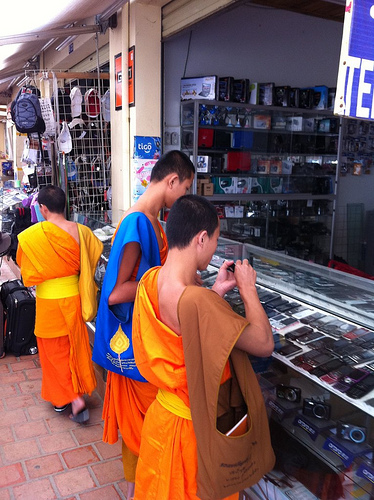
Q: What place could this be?
A: It is a shop.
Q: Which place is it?
A: It is a shop.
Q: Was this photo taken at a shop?
A: Yes, it was taken in a shop.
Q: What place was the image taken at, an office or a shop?
A: It was taken at a shop.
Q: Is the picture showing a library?
A: No, the picture is showing a shop.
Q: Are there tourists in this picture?
A: No, there are no tourists.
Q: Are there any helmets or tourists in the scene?
A: No, there are no tourists or helmets.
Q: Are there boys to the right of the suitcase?
A: No, there is a man to the right of the suitcase.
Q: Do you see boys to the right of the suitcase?
A: No, there is a man to the right of the suitcase.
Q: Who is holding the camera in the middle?
A: The man is holding the camera.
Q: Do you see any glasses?
A: No, there are no glasses.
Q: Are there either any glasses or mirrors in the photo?
A: No, there are no glasses or mirrors.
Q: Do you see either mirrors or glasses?
A: No, there are no glasses or mirrors.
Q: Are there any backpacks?
A: Yes, there is a backpack.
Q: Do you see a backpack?
A: Yes, there is a backpack.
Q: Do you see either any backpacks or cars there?
A: Yes, there is a backpack.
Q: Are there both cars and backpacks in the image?
A: No, there is a backpack but no cars.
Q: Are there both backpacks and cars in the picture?
A: No, there is a backpack but no cars.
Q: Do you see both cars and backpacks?
A: No, there is a backpack but no cars.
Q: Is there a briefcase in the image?
A: No, there are no briefcases.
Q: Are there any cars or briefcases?
A: No, there are no briefcases or cars.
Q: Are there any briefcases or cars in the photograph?
A: No, there are no briefcases or cars.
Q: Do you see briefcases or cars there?
A: No, there are no briefcases or cars.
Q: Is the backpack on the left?
A: Yes, the backpack is on the left of the image.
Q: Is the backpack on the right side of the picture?
A: No, the backpack is on the left of the image.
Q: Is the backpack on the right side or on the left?
A: The backpack is on the left of the image.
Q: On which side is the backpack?
A: The backpack is on the left of the image.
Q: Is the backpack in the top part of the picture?
A: Yes, the backpack is in the top of the image.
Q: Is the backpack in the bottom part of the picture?
A: No, the backpack is in the top of the image.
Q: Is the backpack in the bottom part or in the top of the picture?
A: The backpack is in the top of the image.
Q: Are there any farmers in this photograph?
A: No, there are no farmers.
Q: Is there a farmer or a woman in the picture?
A: No, there are no farmers or women.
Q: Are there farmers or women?
A: No, there are no farmers or women.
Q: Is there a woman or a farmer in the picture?
A: No, there are no farmers or women.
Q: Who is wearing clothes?
A: The man is wearing clothes.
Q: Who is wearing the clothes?
A: The man is wearing clothes.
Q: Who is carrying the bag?
A: The man is carrying the bag.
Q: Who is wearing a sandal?
A: The man is wearing a sandal.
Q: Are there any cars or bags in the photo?
A: Yes, there is a bag.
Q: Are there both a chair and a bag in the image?
A: No, there is a bag but no chairs.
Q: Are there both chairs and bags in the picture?
A: No, there is a bag but no chairs.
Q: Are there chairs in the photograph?
A: No, there are no chairs.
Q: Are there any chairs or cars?
A: No, there are no chairs or cars.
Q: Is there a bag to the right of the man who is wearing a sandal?
A: Yes, there is a bag to the right of the man.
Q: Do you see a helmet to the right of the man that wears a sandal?
A: No, there is a bag to the right of the man.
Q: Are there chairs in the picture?
A: No, there are no chairs.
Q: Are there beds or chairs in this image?
A: No, there are no chairs or beds.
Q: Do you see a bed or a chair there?
A: No, there are no chairs or beds.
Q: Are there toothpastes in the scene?
A: No, there are no toothpastes.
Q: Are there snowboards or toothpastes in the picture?
A: No, there are no toothpastes or snowboards.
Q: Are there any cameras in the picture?
A: Yes, there is a camera.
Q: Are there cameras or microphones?
A: Yes, there is a camera.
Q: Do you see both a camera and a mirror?
A: No, there is a camera but no mirrors.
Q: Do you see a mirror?
A: No, there are no mirrors.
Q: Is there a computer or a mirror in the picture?
A: No, there are no mirrors or computers.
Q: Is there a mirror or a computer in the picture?
A: No, there are no mirrors or computers.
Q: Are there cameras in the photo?
A: Yes, there is a camera.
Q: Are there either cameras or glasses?
A: Yes, there is a camera.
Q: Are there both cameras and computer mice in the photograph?
A: No, there is a camera but no computer mice.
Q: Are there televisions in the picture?
A: No, there are no televisions.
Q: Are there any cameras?
A: Yes, there is a camera.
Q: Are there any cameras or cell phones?
A: Yes, there is a camera.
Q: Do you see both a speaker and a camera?
A: No, there is a camera but no speakers.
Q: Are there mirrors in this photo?
A: No, there are no mirrors.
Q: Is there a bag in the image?
A: Yes, there is a bag.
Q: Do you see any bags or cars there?
A: Yes, there is a bag.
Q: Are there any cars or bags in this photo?
A: Yes, there is a bag.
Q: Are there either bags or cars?
A: Yes, there is a bag.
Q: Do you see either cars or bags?
A: Yes, there is a bag.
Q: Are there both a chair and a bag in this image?
A: No, there is a bag but no chairs.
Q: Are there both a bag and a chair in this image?
A: No, there is a bag but no chairs.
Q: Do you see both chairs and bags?
A: No, there is a bag but no chairs.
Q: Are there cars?
A: No, there are no cars.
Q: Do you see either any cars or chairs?
A: No, there are no cars or chairs.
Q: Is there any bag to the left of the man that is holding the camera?
A: Yes, there is a bag to the left of the man.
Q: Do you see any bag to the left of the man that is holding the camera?
A: Yes, there is a bag to the left of the man.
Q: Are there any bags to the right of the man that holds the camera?
A: No, the bag is to the left of the man.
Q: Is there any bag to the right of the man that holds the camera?
A: No, the bag is to the left of the man.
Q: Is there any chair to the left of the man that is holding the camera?
A: No, there is a bag to the left of the man.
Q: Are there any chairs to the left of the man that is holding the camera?
A: No, there is a bag to the left of the man.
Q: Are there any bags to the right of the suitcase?
A: Yes, there is a bag to the right of the suitcase.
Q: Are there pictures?
A: No, there are no pictures.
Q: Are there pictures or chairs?
A: No, there are no pictures or chairs.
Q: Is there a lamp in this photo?
A: No, there are no lamps.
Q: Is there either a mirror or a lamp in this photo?
A: No, there are no lamps or mirrors.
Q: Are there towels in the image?
A: No, there are no towels.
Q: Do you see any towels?
A: No, there are no towels.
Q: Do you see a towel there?
A: No, there are no towels.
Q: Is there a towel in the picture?
A: No, there are no towels.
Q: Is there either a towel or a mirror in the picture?
A: No, there are no towels or mirrors.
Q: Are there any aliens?
A: No, there are no aliens.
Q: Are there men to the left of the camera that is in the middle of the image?
A: Yes, there is a man to the left of the camera.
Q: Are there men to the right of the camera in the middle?
A: No, the man is to the left of the camera.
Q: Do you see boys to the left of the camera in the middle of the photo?
A: No, there is a man to the left of the camera.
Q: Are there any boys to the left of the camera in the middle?
A: No, there is a man to the left of the camera.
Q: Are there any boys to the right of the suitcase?
A: No, there is a man to the right of the suitcase.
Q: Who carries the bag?
A: The man carries the bag.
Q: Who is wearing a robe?
A: The man is wearing a robe.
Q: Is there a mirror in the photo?
A: No, there are no mirrors.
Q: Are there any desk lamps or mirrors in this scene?
A: No, there are no mirrors or desk lamps.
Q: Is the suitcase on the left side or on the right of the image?
A: The suitcase is on the left of the image.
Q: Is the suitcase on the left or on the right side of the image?
A: The suitcase is on the left of the image.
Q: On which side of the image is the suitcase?
A: The suitcase is on the left of the image.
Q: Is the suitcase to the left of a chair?
A: No, the suitcase is to the left of the bag.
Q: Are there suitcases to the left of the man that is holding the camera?
A: Yes, there is a suitcase to the left of the man.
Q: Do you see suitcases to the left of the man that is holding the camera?
A: Yes, there is a suitcase to the left of the man.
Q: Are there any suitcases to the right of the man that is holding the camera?
A: No, the suitcase is to the left of the man.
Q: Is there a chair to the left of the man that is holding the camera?
A: No, there is a suitcase to the left of the man.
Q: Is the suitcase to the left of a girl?
A: No, the suitcase is to the left of a man.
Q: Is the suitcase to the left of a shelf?
A: No, the suitcase is to the left of the bag.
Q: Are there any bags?
A: Yes, there is a bag.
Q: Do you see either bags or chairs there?
A: Yes, there is a bag.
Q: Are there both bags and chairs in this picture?
A: No, there is a bag but no chairs.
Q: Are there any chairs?
A: No, there are no chairs.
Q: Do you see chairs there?
A: No, there are no chairs.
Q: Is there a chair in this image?
A: No, there are no chairs.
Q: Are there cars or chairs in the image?
A: No, there are no chairs or cars.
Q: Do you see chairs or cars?
A: No, there are no chairs or cars.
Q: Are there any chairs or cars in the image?
A: No, there are no chairs or cars.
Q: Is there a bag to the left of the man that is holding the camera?
A: Yes, there is a bag to the left of the man.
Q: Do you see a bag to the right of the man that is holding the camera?
A: No, the bag is to the left of the man.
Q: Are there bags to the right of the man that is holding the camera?
A: No, the bag is to the left of the man.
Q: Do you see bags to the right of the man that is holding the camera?
A: No, the bag is to the left of the man.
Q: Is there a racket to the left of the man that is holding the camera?
A: No, there is a bag to the left of the man.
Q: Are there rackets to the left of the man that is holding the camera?
A: No, there is a bag to the left of the man.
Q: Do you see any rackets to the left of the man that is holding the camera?
A: No, there is a bag to the left of the man.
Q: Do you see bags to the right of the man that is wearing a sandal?
A: Yes, there is a bag to the right of the man.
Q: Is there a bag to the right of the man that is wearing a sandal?
A: Yes, there is a bag to the right of the man.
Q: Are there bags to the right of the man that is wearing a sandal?
A: Yes, there is a bag to the right of the man.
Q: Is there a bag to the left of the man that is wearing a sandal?
A: No, the bag is to the right of the man.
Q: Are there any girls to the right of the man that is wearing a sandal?
A: No, there is a bag to the right of the man.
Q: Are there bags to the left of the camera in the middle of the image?
A: Yes, there is a bag to the left of the camera.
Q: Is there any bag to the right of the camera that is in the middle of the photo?
A: No, the bag is to the left of the camera.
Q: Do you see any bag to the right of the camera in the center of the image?
A: No, the bag is to the left of the camera.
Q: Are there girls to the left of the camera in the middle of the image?
A: No, there is a bag to the left of the camera.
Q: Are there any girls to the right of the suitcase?
A: No, there is a bag to the right of the suitcase.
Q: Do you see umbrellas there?
A: No, there are no umbrellas.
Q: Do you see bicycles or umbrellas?
A: No, there are no umbrellas or bicycles.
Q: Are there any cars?
A: No, there are no cars.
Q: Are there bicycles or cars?
A: No, there are no cars or bicycles.